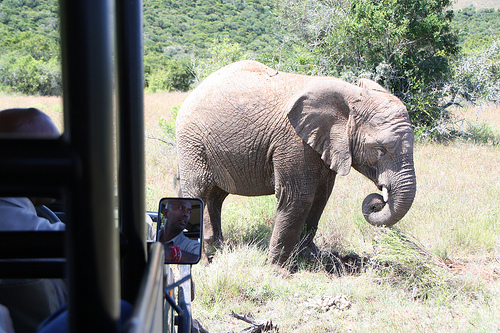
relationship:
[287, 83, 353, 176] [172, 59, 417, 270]
ear of elephant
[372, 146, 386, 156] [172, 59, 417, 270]
eye of elephant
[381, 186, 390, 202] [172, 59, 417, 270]
tusk of elephant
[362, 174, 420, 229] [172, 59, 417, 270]
trunk of elephant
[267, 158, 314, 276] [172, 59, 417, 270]
leg of elephant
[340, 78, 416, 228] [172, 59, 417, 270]
head of elephant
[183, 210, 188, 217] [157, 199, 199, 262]
nose of person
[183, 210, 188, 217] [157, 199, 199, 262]
nose of man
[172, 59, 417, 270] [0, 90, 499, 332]
elephant in grass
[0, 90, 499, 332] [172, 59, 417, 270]
grass behind elephant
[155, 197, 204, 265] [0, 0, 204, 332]
mirror on vehicle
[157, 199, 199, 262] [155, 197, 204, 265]
man in mirror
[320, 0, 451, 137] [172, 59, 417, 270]
tree behind elephant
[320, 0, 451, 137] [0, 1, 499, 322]
tree in background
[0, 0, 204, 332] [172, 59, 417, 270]
vehicle in front of elephant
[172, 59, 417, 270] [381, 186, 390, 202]
elephant has tusk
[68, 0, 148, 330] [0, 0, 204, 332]
bars on vehicle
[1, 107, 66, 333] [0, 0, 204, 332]
man driving vehicle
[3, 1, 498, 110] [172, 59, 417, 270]
foliage behind elephant